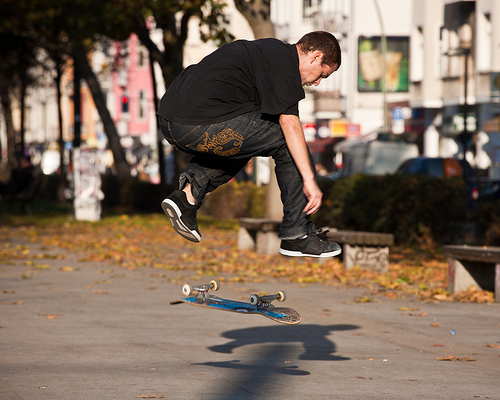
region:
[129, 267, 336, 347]
a blue skateboard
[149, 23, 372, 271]
skateboarder getting air time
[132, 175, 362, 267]
black skate shoes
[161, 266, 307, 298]
upside down skate trucks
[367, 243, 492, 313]
fallen leaves on the ground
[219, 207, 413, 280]
stone park benches in the background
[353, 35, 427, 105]
sign advertisement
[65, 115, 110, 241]
a notification board in the background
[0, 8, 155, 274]
trees losing their leaves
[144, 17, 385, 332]
a skateboard trick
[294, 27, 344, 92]
the head of a man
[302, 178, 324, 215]
the hand of a man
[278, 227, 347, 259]
the foot of a man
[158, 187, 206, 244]
a black and white shoe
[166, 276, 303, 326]
a skateboard in the air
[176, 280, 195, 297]
the white wheel of a skateboard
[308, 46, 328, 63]
the ear of a man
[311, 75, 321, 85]
the nose of a man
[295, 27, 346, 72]
the hair of the man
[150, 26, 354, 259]
a man in the air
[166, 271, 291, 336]
a skateboard up in the air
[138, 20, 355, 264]
a person up in the air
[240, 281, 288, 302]
a pair of the skateboard's wheels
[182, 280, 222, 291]
a pair of the skateboard's wheels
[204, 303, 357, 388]
the person's shadow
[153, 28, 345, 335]
a person skateboarding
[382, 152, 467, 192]
a vehicle in a distance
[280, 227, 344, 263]
a black shoe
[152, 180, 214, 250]
another black shoe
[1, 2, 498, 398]
it is a sunny day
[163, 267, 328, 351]
upside down skateboard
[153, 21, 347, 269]
skateboarder hovers in the air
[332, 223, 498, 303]
concrete benches by the sidewalk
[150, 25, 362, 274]
a guy in a black shirt skateboards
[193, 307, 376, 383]
a skateboarders shadow on the ground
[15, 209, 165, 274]
fall leaves cover the ground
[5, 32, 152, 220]
blurry buildings in the background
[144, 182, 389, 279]
black shoes with white soles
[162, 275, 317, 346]
white wheels on a blue skateboard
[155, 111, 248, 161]
jeans with a design on the pocket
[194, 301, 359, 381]
the shadow of a person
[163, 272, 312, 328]
a skating board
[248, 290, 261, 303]
the wheel of a skateboard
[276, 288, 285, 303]
the wheel of a skateboard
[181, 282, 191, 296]
the wheel of a skateboard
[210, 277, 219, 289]
the wheel of a skateboard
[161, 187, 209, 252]
a black shoe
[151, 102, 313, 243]
a black design jeans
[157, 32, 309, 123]
a black t-shirt